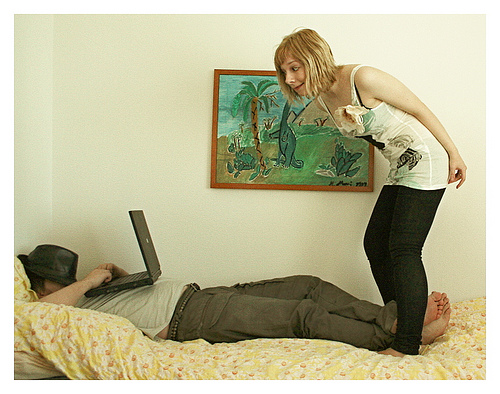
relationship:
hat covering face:
[17, 243, 79, 283] [34, 273, 65, 291]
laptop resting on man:
[92, 215, 169, 299] [79, 277, 193, 327]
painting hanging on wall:
[212, 67, 374, 194] [19, 15, 493, 297]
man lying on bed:
[16, 243, 453, 354] [14, 259, 479, 383]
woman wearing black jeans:
[265, 23, 472, 356] [362, 180, 446, 355]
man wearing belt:
[16, 243, 453, 354] [161, 273, 187, 341]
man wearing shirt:
[12, 241, 452, 358] [77, 280, 186, 342]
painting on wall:
[208, 67, 375, 193] [19, 15, 493, 297]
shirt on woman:
[309, 67, 452, 189] [265, 23, 472, 356]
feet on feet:
[419, 291, 452, 343] [419, 281, 458, 348]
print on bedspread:
[95, 344, 407, 379] [15, 256, 485, 380]